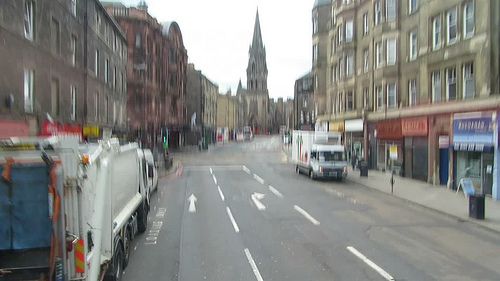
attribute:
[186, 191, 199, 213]
arrow — white, straight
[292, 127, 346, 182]
van — white, parked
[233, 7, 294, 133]
building — tall, old, church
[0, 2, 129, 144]
building — old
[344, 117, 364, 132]
sign — white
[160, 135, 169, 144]
light — green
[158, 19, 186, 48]
roof — curved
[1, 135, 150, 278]
truck — white, parked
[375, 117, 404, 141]
sign — red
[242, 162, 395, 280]
broken lines — white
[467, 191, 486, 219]
trash bin — black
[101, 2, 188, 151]
building — red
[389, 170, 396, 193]
parking meter — black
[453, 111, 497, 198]
storefront — blue, painted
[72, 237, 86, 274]
spiral — reflector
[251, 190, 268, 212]
arrow — curved, turning, white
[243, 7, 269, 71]
point — spire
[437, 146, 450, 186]
door — blue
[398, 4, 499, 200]
building — tan